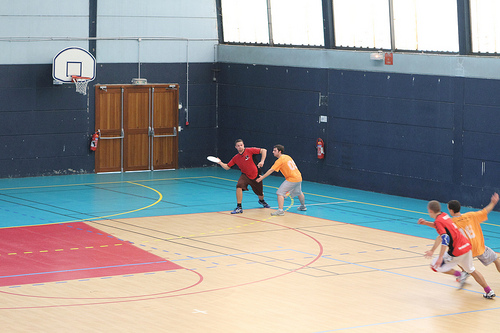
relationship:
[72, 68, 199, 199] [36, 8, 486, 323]
door in a building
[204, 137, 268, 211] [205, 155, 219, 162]
man holding frisbee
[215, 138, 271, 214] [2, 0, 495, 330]
man playing in building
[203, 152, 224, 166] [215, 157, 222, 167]
frisbee in hand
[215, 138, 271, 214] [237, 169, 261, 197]
man wearing brown shorts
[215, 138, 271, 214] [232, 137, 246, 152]
man has head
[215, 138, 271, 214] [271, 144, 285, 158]
man has head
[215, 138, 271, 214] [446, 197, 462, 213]
man has head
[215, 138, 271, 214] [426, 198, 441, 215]
man has head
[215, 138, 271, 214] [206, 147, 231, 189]
man has arm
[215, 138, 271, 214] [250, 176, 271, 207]
man has leg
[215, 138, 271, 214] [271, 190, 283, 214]
man has leg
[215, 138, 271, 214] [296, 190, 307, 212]
man has leg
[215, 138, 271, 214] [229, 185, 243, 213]
man has leg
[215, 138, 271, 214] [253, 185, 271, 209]
man has leg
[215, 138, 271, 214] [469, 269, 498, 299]
man has leg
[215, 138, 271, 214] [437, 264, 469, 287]
man has leg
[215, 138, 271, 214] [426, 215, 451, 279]
man has arm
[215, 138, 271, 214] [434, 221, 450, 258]
man has arm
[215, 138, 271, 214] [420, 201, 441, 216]
man has head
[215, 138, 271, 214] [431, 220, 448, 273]
man has arm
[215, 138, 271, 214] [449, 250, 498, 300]
man has leg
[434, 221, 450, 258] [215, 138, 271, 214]
arm of man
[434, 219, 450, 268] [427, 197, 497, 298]
arm of person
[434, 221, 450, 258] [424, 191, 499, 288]
arm of person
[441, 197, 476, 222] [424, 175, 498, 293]
head of person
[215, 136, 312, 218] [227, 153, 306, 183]
boys wearing jersey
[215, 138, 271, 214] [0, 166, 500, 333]
man on basketball court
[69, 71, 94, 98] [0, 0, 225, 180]
basketball hoop on wall